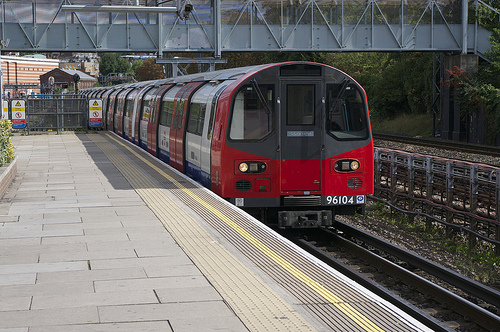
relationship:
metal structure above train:
[2, 4, 472, 67] [75, 54, 410, 214]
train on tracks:
[0, 55, 377, 231] [217, 74, 497, 331]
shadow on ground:
[67, 121, 199, 215] [0, 126, 431, 329]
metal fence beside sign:
[25, 90, 89, 131] [88, 97, 103, 130]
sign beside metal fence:
[8, 96, 25, 129] [25, 90, 89, 131]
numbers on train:
[322, 192, 356, 206] [23, 57, 395, 227]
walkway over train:
[0, 0, 498, 52] [70, 59, 378, 234]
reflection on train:
[90, 80, 233, 133] [23, 42, 383, 232]